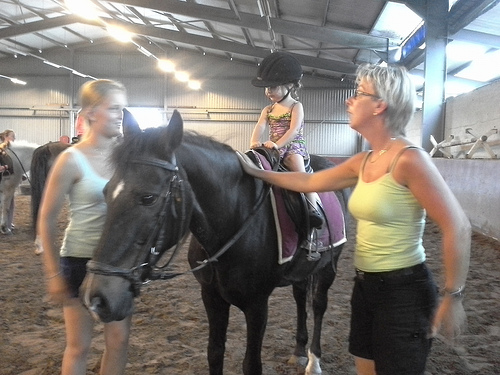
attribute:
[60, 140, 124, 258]
tank top — white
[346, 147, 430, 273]
top — green, tank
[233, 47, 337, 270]
girl — little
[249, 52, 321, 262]
girl — little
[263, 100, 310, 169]
dress — floral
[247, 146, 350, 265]
blanket — red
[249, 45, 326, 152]
girl — little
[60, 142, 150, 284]
shirt — white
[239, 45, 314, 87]
riding helmet — black, small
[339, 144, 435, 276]
top — yellow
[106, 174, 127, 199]
diamond — white